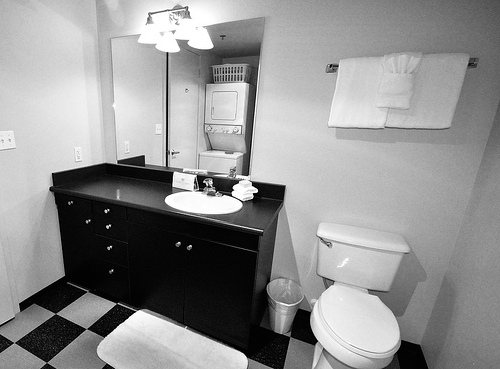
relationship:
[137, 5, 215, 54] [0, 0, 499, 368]
light in bathroom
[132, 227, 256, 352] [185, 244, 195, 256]
cabinet has handle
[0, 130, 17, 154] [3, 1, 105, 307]
switch on wall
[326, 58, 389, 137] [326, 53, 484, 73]
towel on rack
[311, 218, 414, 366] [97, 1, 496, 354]
toilet next to wall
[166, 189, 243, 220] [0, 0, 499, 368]
sink in bathroom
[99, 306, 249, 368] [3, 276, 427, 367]
rug on floor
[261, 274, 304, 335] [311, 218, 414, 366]
can next to toilet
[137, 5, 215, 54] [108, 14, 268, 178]
light next to mirror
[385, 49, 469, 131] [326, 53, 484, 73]
towel on rack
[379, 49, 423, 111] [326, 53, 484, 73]
towel on rack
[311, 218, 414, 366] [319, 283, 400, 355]
toilet has lid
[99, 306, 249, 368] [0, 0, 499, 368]
rug in bathroom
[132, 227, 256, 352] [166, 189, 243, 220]
cabinet under sink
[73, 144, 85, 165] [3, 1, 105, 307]
outlet on wall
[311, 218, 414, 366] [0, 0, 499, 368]
toilet in bathroom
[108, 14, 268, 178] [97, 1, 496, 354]
mirror on wall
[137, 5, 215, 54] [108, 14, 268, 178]
light above mirror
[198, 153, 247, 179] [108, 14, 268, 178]
washer reflected in mirror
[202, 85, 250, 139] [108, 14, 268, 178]
dryer reflected in mirror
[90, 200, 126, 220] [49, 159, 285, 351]
drawer in vanity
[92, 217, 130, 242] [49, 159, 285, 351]
drawer in vanity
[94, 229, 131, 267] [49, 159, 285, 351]
drawer in vanity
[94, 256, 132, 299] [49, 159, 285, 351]
drawer in vanity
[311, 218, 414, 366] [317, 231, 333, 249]
toilet has handle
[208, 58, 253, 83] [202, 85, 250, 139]
basket top of dryer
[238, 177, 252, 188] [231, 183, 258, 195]
soap on washcloth